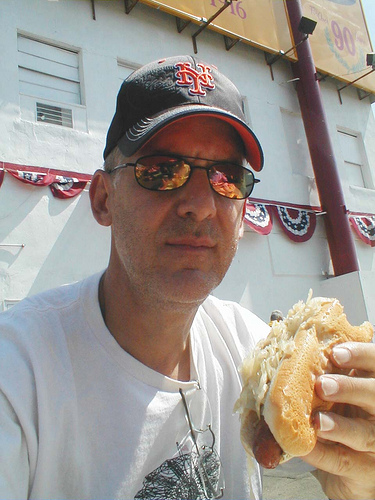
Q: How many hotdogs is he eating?
A: One.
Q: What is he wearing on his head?
A: Cap.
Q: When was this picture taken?
A: Daytime.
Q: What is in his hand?
A: Hot dog.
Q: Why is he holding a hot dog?
A: He is hungry.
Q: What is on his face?
A: Sunglasses.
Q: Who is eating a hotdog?
A: A man.